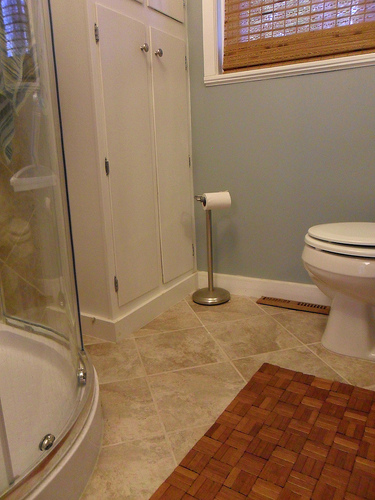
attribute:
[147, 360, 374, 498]
mat — brown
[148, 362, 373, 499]
wood — brown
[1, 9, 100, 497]
shower — clear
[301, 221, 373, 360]
toilet — white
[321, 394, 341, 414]
wood piece — brown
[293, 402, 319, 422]
wood — brown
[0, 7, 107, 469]
bathroom — CLEAR 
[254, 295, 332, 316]
floor vent — brown, wooden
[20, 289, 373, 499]
floor — wood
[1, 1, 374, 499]
bathroom — small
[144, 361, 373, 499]
rug — VINAL 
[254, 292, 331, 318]
vent — BROWN 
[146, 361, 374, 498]
piece — wood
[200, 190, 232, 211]
tissue — white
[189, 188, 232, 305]
holder — golden